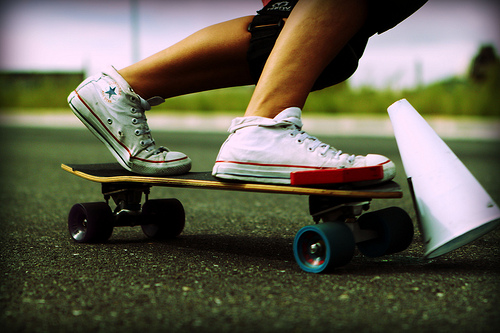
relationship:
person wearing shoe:
[67, 0, 398, 187] [67, 65, 192, 175]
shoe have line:
[67, 65, 192, 175] [74, 89, 188, 163]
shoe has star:
[67, 63, 193, 175] [105, 85, 120, 99]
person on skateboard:
[67, 0, 398, 187] [60, 159, 415, 272]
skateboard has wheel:
[60, 159, 415, 272] [293, 221, 355, 274]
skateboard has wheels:
[60, 159, 415, 272] [68, 198, 415, 258]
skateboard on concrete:
[60, 159, 415, 272] [2, 126, 500, 329]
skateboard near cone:
[60, 159, 415, 272] [387, 98, 500, 263]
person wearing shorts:
[67, 0, 398, 187] [247, 3, 427, 92]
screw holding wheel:
[307, 241, 322, 256] [293, 221, 355, 274]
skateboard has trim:
[60, 159, 415, 272] [58, 162, 405, 199]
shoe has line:
[67, 63, 193, 175] [74, 88, 189, 163]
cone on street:
[387, 98, 500, 263] [0, 128, 496, 329]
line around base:
[74, 88, 189, 163] [67, 89, 192, 175]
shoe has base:
[67, 63, 193, 175] [67, 89, 192, 175]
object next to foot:
[289, 164, 386, 185] [211, 107, 399, 185]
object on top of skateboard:
[289, 164, 386, 185] [60, 159, 415, 272]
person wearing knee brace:
[67, 0, 398, 187] [247, 0, 358, 89]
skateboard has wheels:
[60, 159, 415, 272] [68, 197, 415, 274]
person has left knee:
[67, 0, 398, 187] [248, 1, 369, 90]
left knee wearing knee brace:
[248, 1, 369, 90] [247, 0, 358, 89]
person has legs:
[67, 0, 398, 187] [116, 0, 428, 120]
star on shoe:
[105, 85, 120, 99] [67, 63, 193, 175]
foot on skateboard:
[211, 107, 399, 185] [60, 159, 415, 272]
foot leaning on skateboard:
[67, 64, 193, 175] [60, 159, 415, 272]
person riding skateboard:
[67, 0, 398, 187] [60, 159, 415, 272]